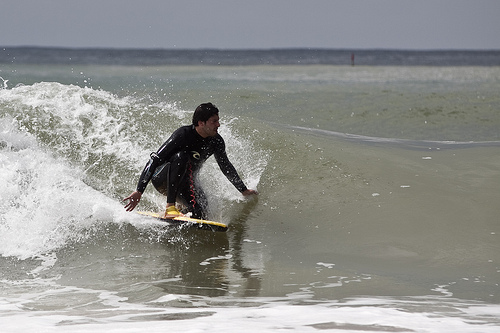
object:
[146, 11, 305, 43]
sky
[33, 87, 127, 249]
sea foam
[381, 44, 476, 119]
ocean surface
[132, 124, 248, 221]
black suit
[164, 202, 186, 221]
foot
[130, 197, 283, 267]
surfboard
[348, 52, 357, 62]
background person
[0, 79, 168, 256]
wave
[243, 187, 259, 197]
hand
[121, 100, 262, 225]
body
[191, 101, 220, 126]
black hair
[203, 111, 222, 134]
face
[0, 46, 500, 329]
ocean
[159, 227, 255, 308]
reflection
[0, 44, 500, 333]
water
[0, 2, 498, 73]
background